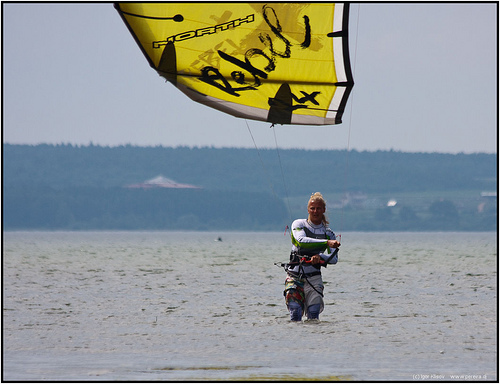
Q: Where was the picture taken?
A: It was taken at the beach.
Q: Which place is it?
A: It is a beach.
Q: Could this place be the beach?
A: Yes, it is the beach.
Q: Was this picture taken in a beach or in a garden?
A: It was taken at a beach.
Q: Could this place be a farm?
A: No, it is a beach.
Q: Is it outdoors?
A: Yes, it is outdoors.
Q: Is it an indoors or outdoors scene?
A: It is outdoors.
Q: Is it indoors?
A: No, it is outdoors.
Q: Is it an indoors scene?
A: No, it is outdoors.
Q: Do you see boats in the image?
A: No, there are no boats.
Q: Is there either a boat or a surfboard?
A: No, there are no boats or surfboards.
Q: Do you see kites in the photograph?
A: Yes, there is a kite.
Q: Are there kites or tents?
A: Yes, there is a kite.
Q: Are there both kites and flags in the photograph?
A: No, there is a kite but no flags.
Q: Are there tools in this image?
A: No, there are no tools.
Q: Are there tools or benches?
A: No, there are no tools or benches.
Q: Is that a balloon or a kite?
A: That is a kite.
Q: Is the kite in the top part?
A: Yes, the kite is in the top of the image.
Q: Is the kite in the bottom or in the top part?
A: The kite is in the top of the image.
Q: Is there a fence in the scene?
A: No, there are no fences.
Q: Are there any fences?
A: No, there are no fences.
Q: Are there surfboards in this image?
A: No, there are no surfboards.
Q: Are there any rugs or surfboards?
A: No, there are no surfboards or rugs.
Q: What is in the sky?
A: The clouds are in the sky.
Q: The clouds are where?
A: The clouds are in the sky.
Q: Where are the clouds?
A: The clouds are in the sky.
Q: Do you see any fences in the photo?
A: No, there are no fences.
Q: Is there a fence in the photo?
A: No, there are no fences.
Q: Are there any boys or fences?
A: No, there are no fences or boys.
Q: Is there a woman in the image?
A: Yes, there is a woman.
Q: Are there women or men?
A: Yes, there is a woman.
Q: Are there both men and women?
A: No, there is a woman but no men.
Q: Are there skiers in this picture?
A: No, there are no skiers.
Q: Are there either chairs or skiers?
A: No, there are no skiers or chairs.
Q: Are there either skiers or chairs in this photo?
A: No, there are no skiers or chairs.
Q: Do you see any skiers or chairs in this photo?
A: No, there are no skiers or chairs.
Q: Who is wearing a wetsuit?
A: The woman is wearing a wetsuit.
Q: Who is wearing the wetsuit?
A: The woman is wearing a wetsuit.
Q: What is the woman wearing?
A: The woman is wearing a wetsuit.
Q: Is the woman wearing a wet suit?
A: Yes, the woman is wearing a wet suit.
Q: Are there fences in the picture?
A: No, there are no fences.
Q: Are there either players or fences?
A: No, there are no fences or players.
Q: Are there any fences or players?
A: No, there are no fences or players.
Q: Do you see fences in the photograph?
A: No, there are no fences.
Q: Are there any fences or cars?
A: No, there are no fences or cars.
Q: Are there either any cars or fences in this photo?
A: No, there are no fences or cars.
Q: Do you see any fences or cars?
A: No, there are no fences or cars.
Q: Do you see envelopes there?
A: No, there are no envelopes.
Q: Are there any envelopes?
A: No, there are no envelopes.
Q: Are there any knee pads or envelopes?
A: No, there are no envelopes or knee pads.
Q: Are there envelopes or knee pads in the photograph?
A: No, there are no envelopes or knee pads.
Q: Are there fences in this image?
A: No, there are no fences.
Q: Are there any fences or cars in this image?
A: No, there are no fences or cars.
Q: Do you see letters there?
A: Yes, there are letters.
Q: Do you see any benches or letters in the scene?
A: Yes, there are letters.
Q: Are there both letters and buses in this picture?
A: No, there are letters but no buses.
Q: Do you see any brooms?
A: No, there are no brooms.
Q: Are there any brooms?
A: No, there are no brooms.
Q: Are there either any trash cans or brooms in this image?
A: No, there are no brooms or trash cans.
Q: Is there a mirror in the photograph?
A: No, there are no mirrors.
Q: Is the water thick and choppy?
A: Yes, the water is thick and choppy.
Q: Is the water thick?
A: Yes, the water is thick.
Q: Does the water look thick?
A: Yes, the water is thick.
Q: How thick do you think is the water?
A: The water is thick.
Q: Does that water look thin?
A: No, the water is thick.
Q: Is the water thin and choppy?
A: No, the water is choppy but thick.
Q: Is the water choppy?
A: Yes, the water is choppy.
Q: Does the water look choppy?
A: Yes, the water is choppy.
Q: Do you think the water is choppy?
A: Yes, the water is choppy.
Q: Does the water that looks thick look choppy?
A: Yes, the water is choppy.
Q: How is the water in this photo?
A: The water is choppy.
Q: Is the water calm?
A: No, the water is choppy.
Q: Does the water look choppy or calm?
A: The water is choppy.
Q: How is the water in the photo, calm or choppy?
A: The water is choppy.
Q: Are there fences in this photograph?
A: No, there are no fences.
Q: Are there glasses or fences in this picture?
A: No, there are no fences or glasses.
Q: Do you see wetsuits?
A: Yes, there is a wetsuit.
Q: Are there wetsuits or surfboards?
A: Yes, there is a wetsuit.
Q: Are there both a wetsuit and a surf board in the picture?
A: No, there is a wetsuit but no surfboards.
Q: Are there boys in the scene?
A: No, there are no boys.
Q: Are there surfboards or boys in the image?
A: No, there are no boys or surfboards.